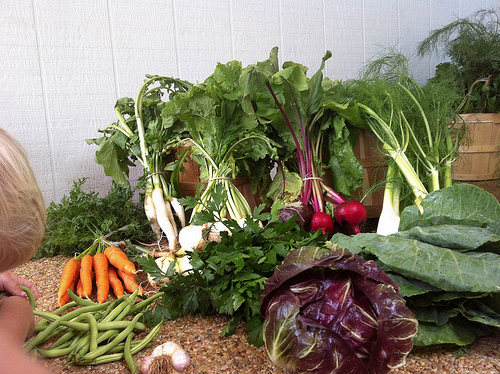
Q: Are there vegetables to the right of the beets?
A: Yes, there is a vegetable to the right of the beets.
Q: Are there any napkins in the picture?
A: No, there are no napkins.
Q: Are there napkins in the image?
A: No, there are no napkins.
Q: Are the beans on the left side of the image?
A: Yes, the beans are on the left of the image.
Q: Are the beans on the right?
A: No, the beans are on the left of the image.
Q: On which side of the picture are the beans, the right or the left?
A: The beans are on the left of the image.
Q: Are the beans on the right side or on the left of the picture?
A: The beans are on the left of the image.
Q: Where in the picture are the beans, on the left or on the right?
A: The beans are on the left of the image.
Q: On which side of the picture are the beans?
A: The beans are on the left of the image.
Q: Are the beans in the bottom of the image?
A: Yes, the beans are in the bottom of the image.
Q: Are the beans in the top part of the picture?
A: No, the beans are in the bottom of the image.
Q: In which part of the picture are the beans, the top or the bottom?
A: The beans are in the bottom of the image.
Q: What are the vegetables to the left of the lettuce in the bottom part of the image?
A: The vegetables are beans.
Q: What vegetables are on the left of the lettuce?
A: The vegetables are beans.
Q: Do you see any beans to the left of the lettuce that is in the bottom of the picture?
A: Yes, there are beans to the left of the lettuce.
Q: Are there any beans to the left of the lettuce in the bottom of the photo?
A: Yes, there are beans to the left of the lettuce.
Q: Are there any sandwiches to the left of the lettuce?
A: No, there are beans to the left of the lettuce.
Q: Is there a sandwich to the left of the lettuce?
A: No, there are beans to the left of the lettuce.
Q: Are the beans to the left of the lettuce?
A: Yes, the beans are to the left of the lettuce.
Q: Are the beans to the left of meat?
A: No, the beans are to the left of the lettuce.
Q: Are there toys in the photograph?
A: No, there are no toys.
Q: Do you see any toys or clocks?
A: No, there are no toys or clocks.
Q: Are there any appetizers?
A: No, there are no appetizers.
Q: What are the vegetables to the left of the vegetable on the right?
A: The vegetables are beets.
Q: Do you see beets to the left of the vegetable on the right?
A: Yes, there are beets to the left of the vegetable.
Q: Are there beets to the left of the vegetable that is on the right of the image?
A: Yes, there are beets to the left of the vegetable.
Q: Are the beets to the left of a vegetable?
A: Yes, the beets are to the left of a vegetable.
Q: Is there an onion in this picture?
A: Yes, there are onions.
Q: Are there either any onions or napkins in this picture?
A: Yes, there are onions.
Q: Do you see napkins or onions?
A: Yes, there are onions.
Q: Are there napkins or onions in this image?
A: Yes, there are onions.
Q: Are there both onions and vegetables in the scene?
A: Yes, there are both onions and vegetables.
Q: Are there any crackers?
A: No, there are no crackers.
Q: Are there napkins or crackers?
A: No, there are no crackers or napkins.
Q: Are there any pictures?
A: No, there are no pictures.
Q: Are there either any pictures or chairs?
A: No, there are no pictures or chairs.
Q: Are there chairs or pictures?
A: No, there are no pictures or chairs.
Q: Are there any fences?
A: No, there are no fences.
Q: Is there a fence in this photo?
A: No, there are no fences.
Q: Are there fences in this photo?
A: No, there are no fences.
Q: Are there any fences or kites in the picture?
A: No, there are no fences or kites.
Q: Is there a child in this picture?
A: Yes, there is a child.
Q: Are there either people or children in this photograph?
A: Yes, there is a child.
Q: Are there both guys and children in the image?
A: No, there is a child but no guys.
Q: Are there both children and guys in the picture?
A: No, there is a child but no guys.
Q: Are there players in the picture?
A: No, there are no players.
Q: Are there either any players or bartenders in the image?
A: No, there are no players or bartenders.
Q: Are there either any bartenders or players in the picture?
A: No, there are no players or bartenders.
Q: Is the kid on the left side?
A: Yes, the kid is on the left of the image.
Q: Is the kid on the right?
A: No, the kid is on the left of the image.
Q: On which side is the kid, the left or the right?
A: The kid is on the left of the image.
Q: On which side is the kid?
A: The kid is on the left of the image.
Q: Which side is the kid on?
A: The kid is on the left of the image.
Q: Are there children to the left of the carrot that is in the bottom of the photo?
A: Yes, there is a child to the left of the carrot.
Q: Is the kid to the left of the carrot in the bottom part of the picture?
A: Yes, the kid is to the left of the carrot.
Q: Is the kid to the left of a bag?
A: No, the kid is to the left of the carrot.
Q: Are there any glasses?
A: No, there are no glasses.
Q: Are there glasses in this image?
A: No, there are no glasses.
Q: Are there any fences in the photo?
A: No, there are no fences.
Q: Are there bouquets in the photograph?
A: No, there are no bouquets.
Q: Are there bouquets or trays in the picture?
A: No, there are no bouquets or trays.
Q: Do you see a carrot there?
A: Yes, there is a carrot.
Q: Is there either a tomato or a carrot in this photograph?
A: Yes, there is a carrot.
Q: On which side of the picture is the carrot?
A: The carrot is on the left of the image.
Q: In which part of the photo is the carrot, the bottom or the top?
A: The carrot is in the bottom of the image.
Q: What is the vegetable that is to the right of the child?
A: The vegetable is a carrot.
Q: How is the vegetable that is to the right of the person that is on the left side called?
A: The vegetable is a carrot.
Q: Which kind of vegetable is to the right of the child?
A: The vegetable is a carrot.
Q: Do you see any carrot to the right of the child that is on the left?
A: Yes, there is a carrot to the right of the kid.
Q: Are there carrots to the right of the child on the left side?
A: Yes, there is a carrot to the right of the kid.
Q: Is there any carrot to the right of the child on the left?
A: Yes, there is a carrot to the right of the kid.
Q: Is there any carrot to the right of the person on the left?
A: Yes, there is a carrot to the right of the kid.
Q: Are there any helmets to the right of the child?
A: No, there is a carrot to the right of the child.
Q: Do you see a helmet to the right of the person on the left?
A: No, there is a carrot to the right of the child.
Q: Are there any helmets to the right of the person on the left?
A: No, there is a carrot to the right of the child.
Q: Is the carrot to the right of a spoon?
A: No, the carrot is to the right of the kid.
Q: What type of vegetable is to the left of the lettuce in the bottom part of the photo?
A: The vegetable is a carrot.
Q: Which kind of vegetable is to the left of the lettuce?
A: The vegetable is a carrot.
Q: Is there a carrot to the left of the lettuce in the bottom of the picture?
A: Yes, there is a carrot to the left of the lettuce.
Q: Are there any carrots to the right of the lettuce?
A: No, the carrot is to the left of the lettuce.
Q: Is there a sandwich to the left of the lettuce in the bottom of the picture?
A: No, there is a carrot to the left of the lettuce.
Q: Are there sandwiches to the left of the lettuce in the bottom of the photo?
A: No, there is a carrot to the left of the lettuce.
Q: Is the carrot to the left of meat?
A: No, the carrot is to the left of the lettuce.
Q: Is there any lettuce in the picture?
A: Yes, there is lettuce.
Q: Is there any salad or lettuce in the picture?
A: Yes, there is lettuce.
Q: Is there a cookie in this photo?
A: No, there are no cookies.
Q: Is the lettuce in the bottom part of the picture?
A: Yes, the lettuce is in the bottom of the image.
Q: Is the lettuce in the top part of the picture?
A: No, the lettuce is in the bottom of the image.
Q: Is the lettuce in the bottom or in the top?
A: The lettuce is in the bottom of the image.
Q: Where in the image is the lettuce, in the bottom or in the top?
A: The lettuce is in the bottom of the image.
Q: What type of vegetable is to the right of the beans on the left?
A: The vegetable is lettuce.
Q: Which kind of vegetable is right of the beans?
A: The vegetable is lettuce.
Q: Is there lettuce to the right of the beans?
A: Yes, there is lettuce to the right of the beans.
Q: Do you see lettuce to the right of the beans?
A: Yes, there is lettuce to the right of the beans.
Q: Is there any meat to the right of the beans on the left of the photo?
A: No, there is lettuce to the right of the beans.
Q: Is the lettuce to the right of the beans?
A: Yes, the lettuce is to the right of the beans.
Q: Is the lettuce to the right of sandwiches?
A: No, the lettuce is to the right of the beans.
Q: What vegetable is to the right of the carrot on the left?
A: The vegetable is lettuce.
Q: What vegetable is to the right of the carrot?
A: The vegetable is lettuce.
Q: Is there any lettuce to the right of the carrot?
A: Yes, there is lettuce to the right of the carrot.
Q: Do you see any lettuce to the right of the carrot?
A: Yes, there is lettuce to the right of the carrot.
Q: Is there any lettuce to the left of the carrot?
A: No, the lettuce is to the right of the carrot.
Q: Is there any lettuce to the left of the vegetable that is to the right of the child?
A: No, the lettuce is to the right of the carrot.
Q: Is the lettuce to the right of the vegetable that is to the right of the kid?
A: Yes, the lettuce is to the right of the carrot.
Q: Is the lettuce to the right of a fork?
A: No, the lettuce is to the right of the carrot.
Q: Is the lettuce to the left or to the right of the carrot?
A: The lettuce is to the right of the carrot.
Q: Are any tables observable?
A: Yes, there is a table.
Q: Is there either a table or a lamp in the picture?
A: Yes, there is a table.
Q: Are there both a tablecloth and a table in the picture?
A: No, there is a table but no tablecloths.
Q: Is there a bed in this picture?
A: No, there are no beds.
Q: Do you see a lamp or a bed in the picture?
A: No, there are no beds or lamps.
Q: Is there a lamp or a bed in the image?
A: No, there are no beds or lamps.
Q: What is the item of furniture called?
A: The piece of furniture is a table.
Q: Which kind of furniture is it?
A: The piece of furniture is a table.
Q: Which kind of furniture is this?
A: That is a table.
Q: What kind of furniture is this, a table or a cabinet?
A: That is a table.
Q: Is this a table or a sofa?
A: This is a table.